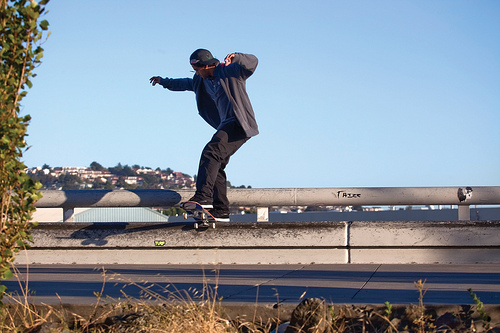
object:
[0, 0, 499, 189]
blue sky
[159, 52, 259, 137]
jacket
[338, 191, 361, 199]
graffiti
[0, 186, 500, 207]
railing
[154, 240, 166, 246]
sticker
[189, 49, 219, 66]
cap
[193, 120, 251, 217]
pants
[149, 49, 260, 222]
he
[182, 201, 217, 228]
skateboard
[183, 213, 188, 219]
wheel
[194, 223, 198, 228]
wheel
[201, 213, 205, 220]
wheel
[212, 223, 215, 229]
wheel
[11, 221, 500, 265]
wall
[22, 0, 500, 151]
cloud